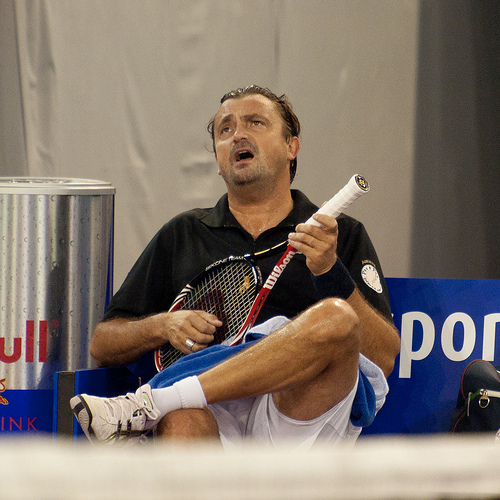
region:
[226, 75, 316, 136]
Man has short hair.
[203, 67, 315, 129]
Man has dark hair.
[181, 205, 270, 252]
Man wearing dark shirt.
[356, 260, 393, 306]
White logo on sleeve.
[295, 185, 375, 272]
White grip on tennis racket.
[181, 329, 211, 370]
Silver ring on man's finger.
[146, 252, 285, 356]
Tennis racket is red, black, and white.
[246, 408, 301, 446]
Man wearing white shorts.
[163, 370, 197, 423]
Man wearing white socks.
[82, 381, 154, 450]
Man wearing white and black shoes.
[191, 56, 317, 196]
head of a person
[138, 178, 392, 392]
person carrying a racket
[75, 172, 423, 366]
person wearing black shirt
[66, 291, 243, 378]
arms of a person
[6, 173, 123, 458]
a big can of red bull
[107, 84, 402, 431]
person sitting on chair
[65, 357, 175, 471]
a pair of white sneakers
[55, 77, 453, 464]
person wearing black shirt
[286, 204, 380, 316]
person wearing a waist band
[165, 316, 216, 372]
a ring on a finger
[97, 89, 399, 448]
Man is holding racket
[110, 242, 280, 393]
Hand is strumming racket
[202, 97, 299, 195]
Man has open mouth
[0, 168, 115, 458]
Large red bull storage next to man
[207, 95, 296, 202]
Man is looking up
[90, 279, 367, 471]
Man has crossed legs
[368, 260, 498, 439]
Blue and white sign behind man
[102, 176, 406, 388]
Black short sleeved polo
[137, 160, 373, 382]
Red white and black racket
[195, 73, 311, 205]
Man has slicked back hair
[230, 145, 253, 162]
The open mouth of a guy strumming a tennis racket.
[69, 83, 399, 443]
A brown haired guy in a black shirt with his mouth open.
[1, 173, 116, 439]
A mostly silver Red Bull can that is giant sized.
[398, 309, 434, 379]
A white letter p beside a man on a bench.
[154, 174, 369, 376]
A white, black and red racket a man is holding.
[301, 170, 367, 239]
White wrapped handle of a tennis racket.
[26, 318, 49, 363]
Two red double l's on the red bull can.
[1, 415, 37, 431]
I N K on the blue part of the red bull can.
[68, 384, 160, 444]
A white and black tennis shoe on a man's left foot.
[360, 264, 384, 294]
A white circle on a man's sleeve.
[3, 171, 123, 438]
Large Red Bull advertising display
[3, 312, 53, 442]
Company identification logo on advertisement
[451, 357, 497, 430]
Athletic bag on bench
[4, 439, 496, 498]
White top of tennis net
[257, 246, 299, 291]
Tennis racket brand identification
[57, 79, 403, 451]
Tennis player sitting on bench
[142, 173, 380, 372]
Tennis racket in man's hands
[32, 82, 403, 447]
Man pretending to play guitar with tennis racket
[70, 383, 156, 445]
White tennis shoes on man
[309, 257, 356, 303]
Black sweatband on wrist